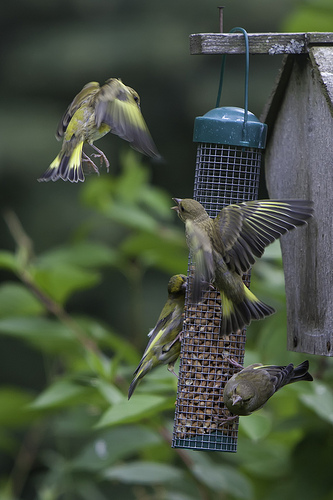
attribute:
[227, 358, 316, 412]
bird — Black 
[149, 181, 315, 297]
bird — yellow and black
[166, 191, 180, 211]
mouth — open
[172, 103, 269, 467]
bird feeder — cylindrical, plastic, wire mesh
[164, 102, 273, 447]
feeder — green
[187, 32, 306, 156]
feeder — green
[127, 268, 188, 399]
bird — gray, yellow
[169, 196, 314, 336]
bird — yellow and black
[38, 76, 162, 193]
bird — yellow and blue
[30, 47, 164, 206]
bird — gray and yellow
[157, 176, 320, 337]
bird — gray and yellow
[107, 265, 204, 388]
bird — gray and yellow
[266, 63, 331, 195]
house — wooden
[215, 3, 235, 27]
nail — rusty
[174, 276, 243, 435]
seeds — brown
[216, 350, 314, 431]
bird — gray and yellow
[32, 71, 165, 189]
bird — yellow and black